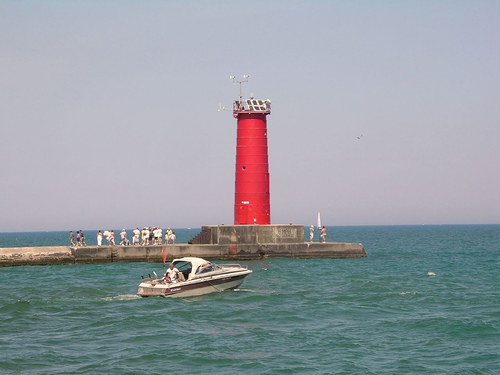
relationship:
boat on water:
[135, 252, 253, 302] [1, 230, 498, 372]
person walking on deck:
[244, 87, 258, 109] [230, 94, 273, 116]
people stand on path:
[68, 227, 176, 248] [3, 243, 367, 263]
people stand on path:
[304, 227, 328, 243] [3, 243, 367, 263]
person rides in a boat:
[159, 259, 181, 284] [135, 252, 253, 302]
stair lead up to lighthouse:
[172, 209, 222, 255] [229, 76, 275, 225]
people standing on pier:
[70, 227, 187, 245] [8, 231, 370, 269]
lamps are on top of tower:
[229, 76, 236, 80] [228, 99, 279, 224]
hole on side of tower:
[240, 163, 248, 173] [229, 94, 274, 228]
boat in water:
[135, 252, 253, 302] [1, 230, 498, 372]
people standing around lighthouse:
[68, 224, 176, 247] [227, 70, 271, 229]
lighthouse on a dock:
[228, 72, 273, 225] [0, 224, 367, 262]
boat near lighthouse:
[135, 252, 253, 302] [227, 93, 269, 230]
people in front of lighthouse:
[304, 222, 318, 245] [218, 67, 293, 231]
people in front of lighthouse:
[315, 218, 329, 245] [218, 67, 293, 231]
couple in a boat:
[164, 265, 182, 284] [136, 256, 253, 301]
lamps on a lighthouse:
[229, 76, 236, 80] [227, 70, 271, 229]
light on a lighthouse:
[242, 72, 250, 81] [227, 70, 271, 229]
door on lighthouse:
[235, 197, 252, 226] [224, 64, 277, 224]